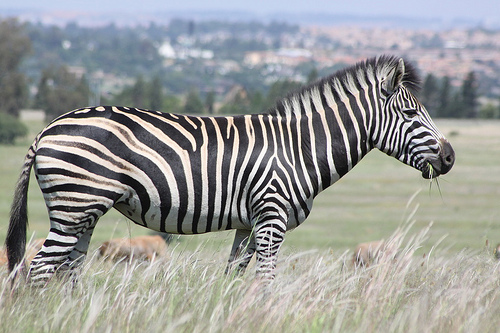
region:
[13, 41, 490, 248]
Zebra in a field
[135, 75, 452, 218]
Zebra in a field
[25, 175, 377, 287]
Zebra in a field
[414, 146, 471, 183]
Zebra eating grass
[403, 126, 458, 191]
Zebra eating grass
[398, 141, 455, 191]
Zebra with a black nose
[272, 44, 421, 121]
Zebra with spiked hair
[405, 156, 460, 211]
Zebra eating grass in the mouth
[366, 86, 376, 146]
black stripe on zebra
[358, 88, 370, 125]
black stripe on zebra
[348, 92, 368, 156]
black stripe on zebra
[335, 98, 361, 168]
black stripe on zebra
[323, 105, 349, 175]
black stripe on zebra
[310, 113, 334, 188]
black stripe on zebra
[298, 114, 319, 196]
black stripe on zebra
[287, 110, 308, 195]
black stripe on zebra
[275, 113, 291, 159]
black stripe on zebra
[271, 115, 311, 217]
black stripe on zebra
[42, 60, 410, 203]
the zebra is black and white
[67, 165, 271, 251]
the black fades to brown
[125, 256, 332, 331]
the grass is overgrown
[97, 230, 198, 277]
animals are behind hte zebra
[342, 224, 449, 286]
animals are in the grass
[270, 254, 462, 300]
the grass is dead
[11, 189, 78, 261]
the zebra has a black tail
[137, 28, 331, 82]
houses are in the hills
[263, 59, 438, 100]
hair is on the zebra's neck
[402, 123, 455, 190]
the horse is eating grass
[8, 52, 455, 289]
a zebra is eating in a field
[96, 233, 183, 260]
a brown animal in the distance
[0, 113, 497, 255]
a large open green field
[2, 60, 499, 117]
blurred pine trees on the horizon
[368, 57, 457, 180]
the head of the zebra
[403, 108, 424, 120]
the right eye of the zebra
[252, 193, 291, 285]
front right leg of a zebra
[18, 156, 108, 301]
back right leg of a zebra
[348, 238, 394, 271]
a light brown animal in the distance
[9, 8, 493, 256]
a blurry background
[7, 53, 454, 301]
zebra grazing in a field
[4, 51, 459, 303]
the zebra is eating grass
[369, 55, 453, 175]
the head of a zebra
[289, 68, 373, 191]
the neck of the zebra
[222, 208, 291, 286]
the front legs of the zebra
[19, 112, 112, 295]
the hind legs of the zebra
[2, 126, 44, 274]
the tail of a zebra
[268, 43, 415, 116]
black and white hair on the zebra's neck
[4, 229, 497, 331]
a field of wheat grass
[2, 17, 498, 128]
blurred background of hills and trees